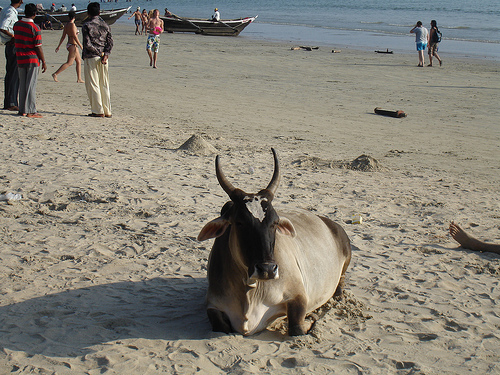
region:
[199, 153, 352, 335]
horned cow on the sand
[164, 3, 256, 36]
two people in a boat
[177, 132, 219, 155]
pile of sand in the shape of a pyramid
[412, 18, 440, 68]
a man and a woman walking near the ocean water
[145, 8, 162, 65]
man wearing swim trunks and holding a frisbee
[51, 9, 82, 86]
woman in a bikini walking on the sand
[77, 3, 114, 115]
man wearing white pants and a dark shirt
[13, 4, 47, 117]
man wearing a red striped shirt and gray pants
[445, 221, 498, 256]
person's foot on the sand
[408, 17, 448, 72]
two people walking near the edge of the water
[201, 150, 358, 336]
cow laying on the sand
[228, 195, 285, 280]
black face of the cow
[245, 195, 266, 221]
white marking on black face of cow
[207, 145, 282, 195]
horns on the cow's head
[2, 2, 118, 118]
people standing on the beach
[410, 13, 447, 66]
two people walking along the water's edge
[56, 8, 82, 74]
woman walking towards the water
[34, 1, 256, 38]
boats on edge of water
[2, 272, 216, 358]
shadow of cow on the sand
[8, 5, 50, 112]
man wearing striped shirt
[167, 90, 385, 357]
this is a cow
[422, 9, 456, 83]
this is a person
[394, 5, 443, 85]
this is a person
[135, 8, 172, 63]
this is a person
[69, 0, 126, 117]
this is a person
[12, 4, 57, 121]
this is a person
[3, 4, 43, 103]
this is a person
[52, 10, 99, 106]
this is a person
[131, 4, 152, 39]
this is a person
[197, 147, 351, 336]
the goat lying on the beach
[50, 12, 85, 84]
the woman in a bikini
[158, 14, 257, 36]
the boat on the sand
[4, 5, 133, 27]
the boat on the sand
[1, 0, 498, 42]
the body of water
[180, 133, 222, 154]
the small mound on the sand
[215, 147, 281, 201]
the horns on the goat's head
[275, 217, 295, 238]
the ear on the goat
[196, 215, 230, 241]
the ear on the goat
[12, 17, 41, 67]
the red and gray striped shirt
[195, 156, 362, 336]
A cow on the beach.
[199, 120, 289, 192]
Horns on the bull.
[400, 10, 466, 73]
People walking on the beach.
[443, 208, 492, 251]
A foot of a person sitting on sand.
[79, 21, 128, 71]
A man with his hands behind his back.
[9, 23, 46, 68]
A man wearing a stripe shirt.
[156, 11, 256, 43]
A boat on the shoreline.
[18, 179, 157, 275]
Footprints in the sand.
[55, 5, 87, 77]
A lady with a bikini.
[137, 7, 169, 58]
A person holding a frisbee.